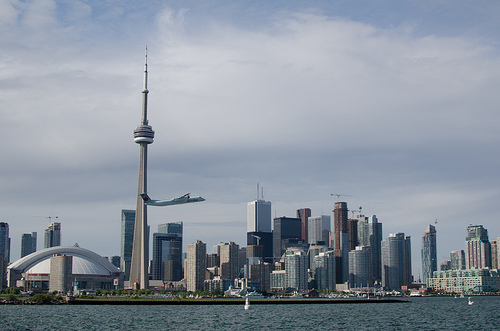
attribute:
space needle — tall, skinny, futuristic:
[128, 44, 154, 290]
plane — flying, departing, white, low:
[136, 191, 206, 206]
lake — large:
[0, 298, 499, 331]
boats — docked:
[317, 283, 403, 301]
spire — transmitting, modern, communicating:
[254, 182, 259, 200]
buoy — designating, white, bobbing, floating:
[242, 297, 249, 311]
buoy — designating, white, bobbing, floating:
[466, 295, 473, 306]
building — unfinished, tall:
[331, 202, 350, 282]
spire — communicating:
[260, 185, 265, 201]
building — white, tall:
[247, 200, 271, 233]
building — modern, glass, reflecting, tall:
[161, 240, 183, 281]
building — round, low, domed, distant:
[6, 246, 121, 296]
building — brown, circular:
[348, 245, 373, 289]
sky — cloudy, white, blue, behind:
[1, 0, 500, 281]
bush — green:
[6, 294, 22, 302]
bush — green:
[31, 293, 55, 303]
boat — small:
[459, 293, 464, 299]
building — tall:
[121, 209, 136, 280]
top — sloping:
[121, 209, 135, 220]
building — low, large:
[428, 270, 500, 295]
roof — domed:
[8, 245, 123, 275]